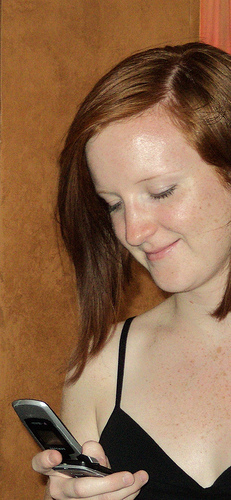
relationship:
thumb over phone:
[80, 436, 108, 470] [74, 448, 113, 474]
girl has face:
[32, 42, 230, 498] [85, 113, 229, 291]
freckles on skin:
[60, 108, 229, 453] [31, 104, 229, 499]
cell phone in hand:
[11, 398, 112, 480] [30, 440, 147, 499]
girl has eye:
[32, 42, 230, 498] [146, 182, 177, 200]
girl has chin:
[32, 42, 230, 498] [147, 247, 198, 291]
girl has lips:
[32, 42, 230, 498] [141, 237, 180, 261]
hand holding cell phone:
[30, 440, 147, 499] [11, 398, 112, 480]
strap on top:
[114, 316, 134, 407] [98, 315, 229, 498]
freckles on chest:
[138, 126, 229, 452] [95, 323, 229, 498]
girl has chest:
[32, 42, 230, 498] [95, 323, 229, 498]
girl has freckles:
[32, 42, 230, 498] [138, 126, 229, 452]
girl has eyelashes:
[32, 42, 230, 498] [147, 184, 176, 201]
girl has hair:
[32, 42, 230, 498] [52, 42, 229, 389]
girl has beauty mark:
[32, 42, 230, 498] [198, 205, 201, 210]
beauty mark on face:
[198, 205, 201, 210] [85, 113, 229, 291]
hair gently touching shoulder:
[52, 42, 229, 389] [61, 293, 175, 409]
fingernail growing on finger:
[47, 451, 58, 464] [30, 448, 62, 475]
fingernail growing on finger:
[122, 472, 133, 485] [49, 468, 134, 498]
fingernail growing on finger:
[136, 469, 149, 482] [65, 468, 148, 499]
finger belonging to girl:
[30, 448, 62, 475] [32, 42, 230, 498]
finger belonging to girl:
[49, 468, 134, 498] [32, 42, 230, 498]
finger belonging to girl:
[65, 468, 148, 499] [32, 42, 230, 498]